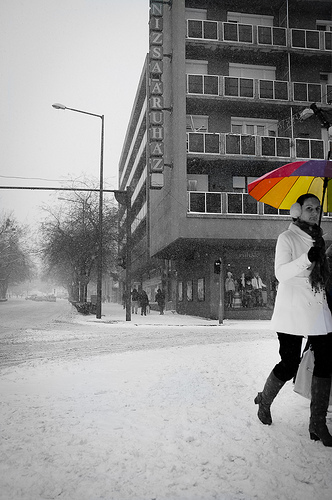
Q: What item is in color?
A: An umbrella.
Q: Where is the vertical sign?
A: On the side of the corner building.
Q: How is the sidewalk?
A: Snow covered.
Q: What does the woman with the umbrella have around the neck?
A: A scarf.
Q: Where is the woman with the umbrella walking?
A: On a sidewalk.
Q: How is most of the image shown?
A: In black and white.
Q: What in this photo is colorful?
A: An umbrella.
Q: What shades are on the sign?
A: Black and white.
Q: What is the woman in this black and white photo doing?
A: Holding a colorful umbrella.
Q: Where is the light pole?
A: On a street corner.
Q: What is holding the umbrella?
A: A lady.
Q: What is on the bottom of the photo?
A: The ground.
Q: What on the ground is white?
A: Snow.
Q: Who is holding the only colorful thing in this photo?
A: The woman.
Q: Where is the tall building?
A: It is in the background.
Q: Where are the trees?
A: On sidewalk.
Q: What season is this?
A: Winter.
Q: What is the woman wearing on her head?
A: Earmuffs.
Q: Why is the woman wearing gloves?
A: Cold weather.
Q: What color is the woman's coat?
A: White.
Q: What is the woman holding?
A: An umbrella.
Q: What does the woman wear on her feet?
A: Boots.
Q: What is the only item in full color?
A: The umbrella.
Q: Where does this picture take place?
A: In a city.